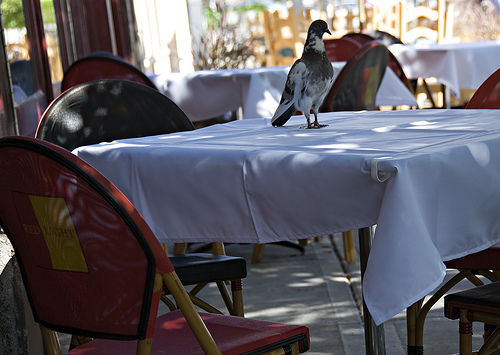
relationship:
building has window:
[0, 0, 198, 140] [2, 0, 43, 109]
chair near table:
[2, 133, 311, 355] [69, 109, 498, 354]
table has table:
[69, 109, 498, 354] [69, 108, 500, 355]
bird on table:
[271, 19, 337, 138] [69, 109, 498, 354]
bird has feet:
[271, 19, 337, 138] [300, 100, 329, 130]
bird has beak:
[271, 19, 337, 138] [324, 24, 333, 36]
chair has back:
[2, 133, 311, 355] [0, 135, 176, 341]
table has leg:
[69, 109, 498, 354] [356, 225, 384, 354]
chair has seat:
[2, 133, 311, 355] [68, 308, 310, 355]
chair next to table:
[2, 133, 311, 355] [69, 109, 498, 354]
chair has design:
[2, 133, 311, 355] [9, 188, 90, 273]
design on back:
[9, 188, 90, 273] [0, 135, 176, 341]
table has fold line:
[69, 108, 500, 355] [238, 143, 270, 246]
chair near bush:
[311, 38, 360, 62] [190, 24, 258, 67]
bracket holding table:
[369, 153, 398, 183] [69, 108, 500, 355]